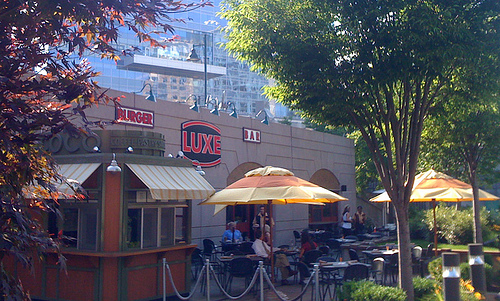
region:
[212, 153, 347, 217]
Yellow and orange umbrella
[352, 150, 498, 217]
Yellow and orange umbrella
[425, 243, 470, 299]
small white and brick barrier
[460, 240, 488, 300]
small white and brick barrier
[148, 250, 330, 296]
SIlver bars with grey ropes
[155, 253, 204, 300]
SIlver bars with grey ropes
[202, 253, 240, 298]
SIlver bars with grey ropes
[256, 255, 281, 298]
SIlver bars with grey ropes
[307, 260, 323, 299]
SIlver bars with grey ropes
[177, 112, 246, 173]
Red and black sign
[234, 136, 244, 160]
part of a building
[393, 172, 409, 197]
part of a branch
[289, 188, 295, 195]
part of an umbrella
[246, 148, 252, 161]
edge of a wall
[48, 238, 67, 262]
part of a leaf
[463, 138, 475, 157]
part of a branch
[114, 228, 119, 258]
part of a shop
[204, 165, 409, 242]
an orange and yellow umbrella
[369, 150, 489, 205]
an orange and yellow umbrella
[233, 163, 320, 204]
an orange and yellow umbrella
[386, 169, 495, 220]
an orange and yellow umbrella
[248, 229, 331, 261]
people sitting on the chair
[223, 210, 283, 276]
people sitting on the chair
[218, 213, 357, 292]
people sitting on the chair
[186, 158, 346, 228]
the umbrella is open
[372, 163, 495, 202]
the umbrella is open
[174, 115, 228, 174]
the text is red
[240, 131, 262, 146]
the text is red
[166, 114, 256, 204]
the text is red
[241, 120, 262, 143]
the text is red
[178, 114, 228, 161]
black and red sign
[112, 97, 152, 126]
red and white sign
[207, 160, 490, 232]
two yellow and pink umbrellas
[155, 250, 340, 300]
white poles and chain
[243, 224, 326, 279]
people sitting under umbrella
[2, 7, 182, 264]
tree with red leaves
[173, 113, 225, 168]
red lettering on black sign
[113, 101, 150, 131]
red lettering on white sign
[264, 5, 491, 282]
two trees by umbrellas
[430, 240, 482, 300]
short poles with lights on them